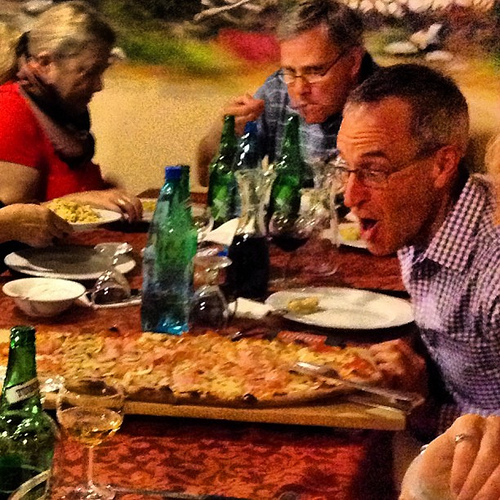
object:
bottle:
[137, 165, 196, 336]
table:
[0, 187, 420, 430]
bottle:
[208, 113, 238, 223]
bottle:
[233, 122, 263, 217]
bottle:
[267, 111, 304, 237]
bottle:
[1, 324, 56, 498]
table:
[1, 414, 393, 499]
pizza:
[2, 323, 382, 408]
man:
[335, 64, 499, 500]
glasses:
[325, 150, 441, 187]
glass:
[269, 208, 309, 288]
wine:
[269, 233, 304, 253]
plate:
[266, 284, 417, 332]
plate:
[4, 245, 136, 280]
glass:
[90, 243, 129, 306]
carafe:
[224, 170, 273, 300]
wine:
[228, 233, 267, 300]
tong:
[286, 360, 416, 417]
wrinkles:
[355, 132, 379, 137]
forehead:
[336, 100, 401, 160]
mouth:
[358, 214, 378, 240]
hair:
[342, 62, 467, 156]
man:
[196, 1, 381, 186]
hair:
[277, 0, 367, 48]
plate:
[138, 198, 205, 224]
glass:
[189, 254, 230, 330]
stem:
[279, 251, 292, 285]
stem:
[205, 269, 217, 286]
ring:
[454, 433, 478, 442]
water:
[138, 295, 191, 337]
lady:
[2, 3, 145, 227]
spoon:
[230, 297, 319, 342]